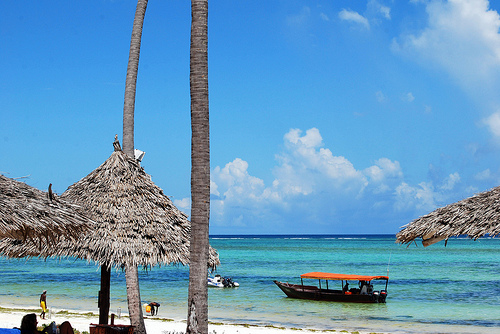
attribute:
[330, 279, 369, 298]
people — few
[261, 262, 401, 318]
boat — brown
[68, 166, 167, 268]
leaves — dried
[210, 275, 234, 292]
raft — white, motorized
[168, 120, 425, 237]
clouds — white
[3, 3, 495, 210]
sky — blue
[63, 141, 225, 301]
canopy — straw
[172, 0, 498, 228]
clouds — white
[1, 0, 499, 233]
sky — blue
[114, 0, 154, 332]
trunk — long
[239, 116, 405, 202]
clouds — white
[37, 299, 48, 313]
pants — yellow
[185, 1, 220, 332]
trunk — tall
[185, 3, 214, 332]
tree — tall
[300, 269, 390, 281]
canopy — orange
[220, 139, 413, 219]
clouds — white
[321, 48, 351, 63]
sky — blue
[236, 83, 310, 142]
clouds — white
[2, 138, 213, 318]
umbrellas — few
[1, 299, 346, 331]
beach — sandy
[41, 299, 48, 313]
swim trunks — yellow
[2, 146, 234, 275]
umbrellas — made of plant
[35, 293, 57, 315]
man — dark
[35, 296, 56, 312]
shorts — yellow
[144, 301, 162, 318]
person — bent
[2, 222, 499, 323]
water — calm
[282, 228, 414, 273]
ocean — blue, clear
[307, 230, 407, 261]
water — calm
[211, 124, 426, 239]
clouds — white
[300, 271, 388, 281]
canopy — orange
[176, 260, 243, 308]
boat — white, motorboat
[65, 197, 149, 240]
leaves — dried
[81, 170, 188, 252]
leaves — dried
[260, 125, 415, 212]
clouds — white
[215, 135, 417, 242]
clouds — white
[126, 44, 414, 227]
sky — blue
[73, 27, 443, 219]
sky — blue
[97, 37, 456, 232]
sky — blue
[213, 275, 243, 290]
engine — black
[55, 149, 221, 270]
umbrella — made of plant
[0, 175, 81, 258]
umbrella — made of plant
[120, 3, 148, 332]
tree — tall